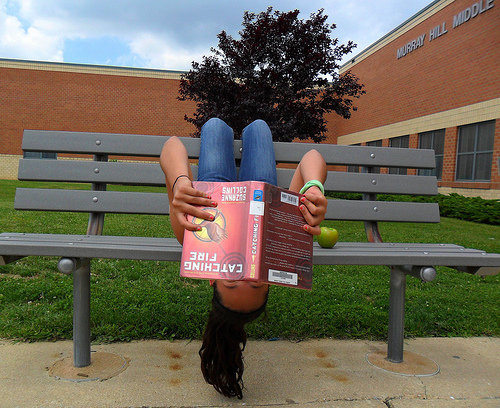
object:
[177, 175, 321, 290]
book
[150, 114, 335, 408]
girl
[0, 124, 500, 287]
bench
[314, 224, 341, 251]
apple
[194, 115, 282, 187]
jeans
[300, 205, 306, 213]
nail polish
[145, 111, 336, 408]
sitting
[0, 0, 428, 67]
sky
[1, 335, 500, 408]
sidewalk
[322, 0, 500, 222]
school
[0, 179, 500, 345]
grass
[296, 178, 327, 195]
bracelet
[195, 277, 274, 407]
hair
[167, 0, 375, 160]
tree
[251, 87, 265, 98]
leaves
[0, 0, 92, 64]
clouds